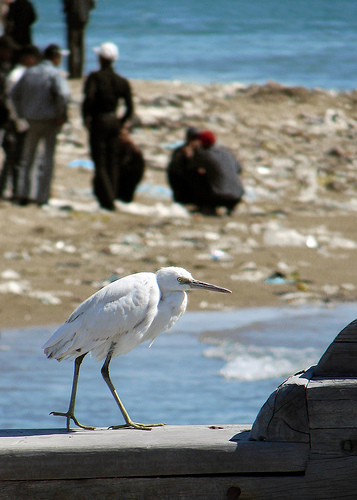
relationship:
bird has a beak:
[44, 266, 232, 436] [190, 278, 229, 295]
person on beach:
[190, 132, 244, 213] [1, 78, 355, 328]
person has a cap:
[190, 132, 244, 213] [92, 45, 117, 59]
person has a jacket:
[190, 132, 244, 213] [190, 148, 244, 199]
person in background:
[190, 132, 244, 213] [1, 2, 355, 314]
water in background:
[27, 2, 354, 95] [1, 2, 355, 314]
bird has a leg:
[44, 266, 232, 436] [102, 346, 132, 422]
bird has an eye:
[44, 266, 232, 436] [180, 278, 188, 286]